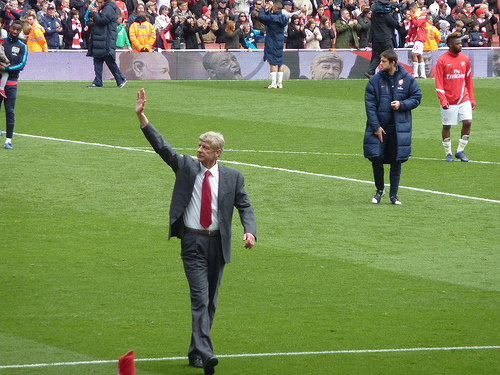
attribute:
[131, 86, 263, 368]
man — waving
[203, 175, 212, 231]
tie — red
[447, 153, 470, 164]
shoes — blue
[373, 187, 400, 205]
shoes — black, white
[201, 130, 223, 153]
hair — grey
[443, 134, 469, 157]
socks — tall, white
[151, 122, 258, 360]
suit — grey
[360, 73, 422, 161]
coat — puffy, dark blue, large, blue, long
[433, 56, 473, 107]
shirt — red, white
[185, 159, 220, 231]
shirt — white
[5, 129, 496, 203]
lines — white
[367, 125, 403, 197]
pants — dark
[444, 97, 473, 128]
shorts — white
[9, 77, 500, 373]
field — green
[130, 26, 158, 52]
jacket — yellow, bright